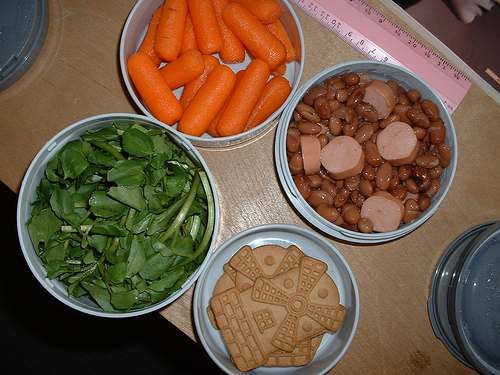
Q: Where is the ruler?
A: On the table.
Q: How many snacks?
A: 4.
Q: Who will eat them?
A: People.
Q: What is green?
A: Salad.